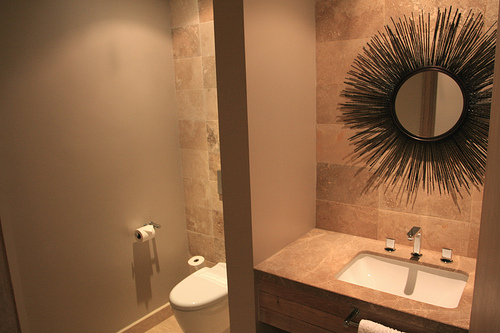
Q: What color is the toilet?
A: White.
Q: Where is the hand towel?
A: On rack in front of sink.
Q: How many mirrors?
A: One.